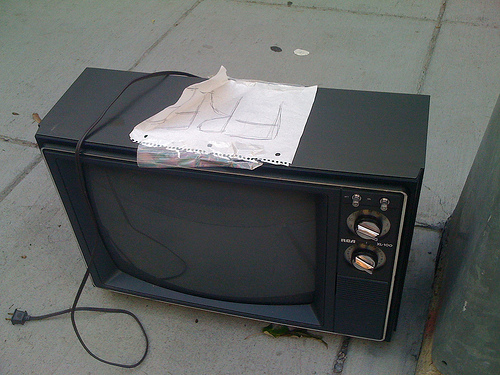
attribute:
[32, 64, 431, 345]
television set — analog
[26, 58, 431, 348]
television — analog, free, old, black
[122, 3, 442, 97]
tile — cemented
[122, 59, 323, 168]
paper — white, old, rumpled, notebook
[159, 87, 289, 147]
writing — black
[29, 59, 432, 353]
tv — CRT, free, old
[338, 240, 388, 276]
knob — gray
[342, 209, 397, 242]
knob — gray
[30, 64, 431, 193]
frame — black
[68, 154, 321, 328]
screen — curved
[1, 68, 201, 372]
cord — black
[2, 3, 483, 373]
sidewalk — gray, cement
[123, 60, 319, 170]
sign — paper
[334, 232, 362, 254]
writing — white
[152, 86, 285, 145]
writing — gray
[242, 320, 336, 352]
leaf — green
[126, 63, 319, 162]
sign — handwritten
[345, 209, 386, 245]
dial — channel-changer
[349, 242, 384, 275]
dial — channel-changer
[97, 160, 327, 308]
screen — old-fashioned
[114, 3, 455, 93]
section — square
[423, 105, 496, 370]
wall — gray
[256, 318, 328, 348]
leaf — green